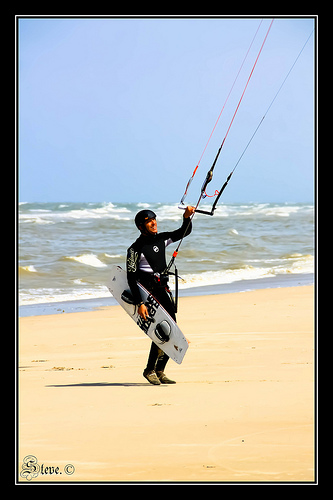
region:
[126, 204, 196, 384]
kiteboarder in a black wetsuit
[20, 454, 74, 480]
black print attributes copyright to Steve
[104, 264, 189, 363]
white kiteboard with black logo design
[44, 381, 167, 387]
black shadow of the kiteboarder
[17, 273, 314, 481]
smooth dry sand beach with wet strip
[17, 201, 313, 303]
turbulent green ocean waters with white capped waves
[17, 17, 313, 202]
cloudless blue sky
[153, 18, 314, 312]
red and black cables connected to a harness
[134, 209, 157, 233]
black helmet on his head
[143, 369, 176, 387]
brown water shoes on his feet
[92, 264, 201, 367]
A wind sailing board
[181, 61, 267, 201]
Wind sailing handle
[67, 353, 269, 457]
Sand on the beach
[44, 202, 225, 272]
Some choppy waves in the water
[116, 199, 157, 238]
Black safety helmit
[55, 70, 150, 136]
Hazy blue sky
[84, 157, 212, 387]
Wearing a wet suit?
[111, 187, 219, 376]
Holding on to the wind sailing kite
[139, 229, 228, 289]
Comnected to the wind sailing kite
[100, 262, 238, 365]
Holding the wind surfing board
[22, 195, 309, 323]
Choppy body of water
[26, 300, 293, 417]
Sandy beach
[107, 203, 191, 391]
A man holding a board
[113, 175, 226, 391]
A man preparing to go parasailing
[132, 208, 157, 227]
A black helmet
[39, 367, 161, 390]
A shadow on the sand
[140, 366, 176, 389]
Brown shoes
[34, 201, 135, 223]
Whitecap waves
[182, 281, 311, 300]
Waterline where wet sand meets dry sand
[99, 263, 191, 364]
White wakeboard with a black design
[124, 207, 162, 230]
man wears black helmet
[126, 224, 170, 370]
man wears black wetsuit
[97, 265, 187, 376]
man has white kiteboard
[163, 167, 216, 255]
man holds black bar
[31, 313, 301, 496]
sand is light brown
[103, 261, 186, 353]
black writing on white board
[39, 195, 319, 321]
water is wavy and choppy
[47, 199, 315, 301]
white caps on waves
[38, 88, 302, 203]
sky is hazy and blue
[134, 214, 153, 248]
man is smiling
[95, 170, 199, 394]
person in black wet suit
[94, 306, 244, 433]
person standing on beach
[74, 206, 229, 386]
person holding white surfboard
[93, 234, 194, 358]
white board with black lettering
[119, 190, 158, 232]
person wearing black hat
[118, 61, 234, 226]
black bar with three cords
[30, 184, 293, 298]
waves in ocean crashing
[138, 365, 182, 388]
brown beach shoes in photo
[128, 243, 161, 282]
white and grey on black wetsuit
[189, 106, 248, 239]
orange cords attached to black bar